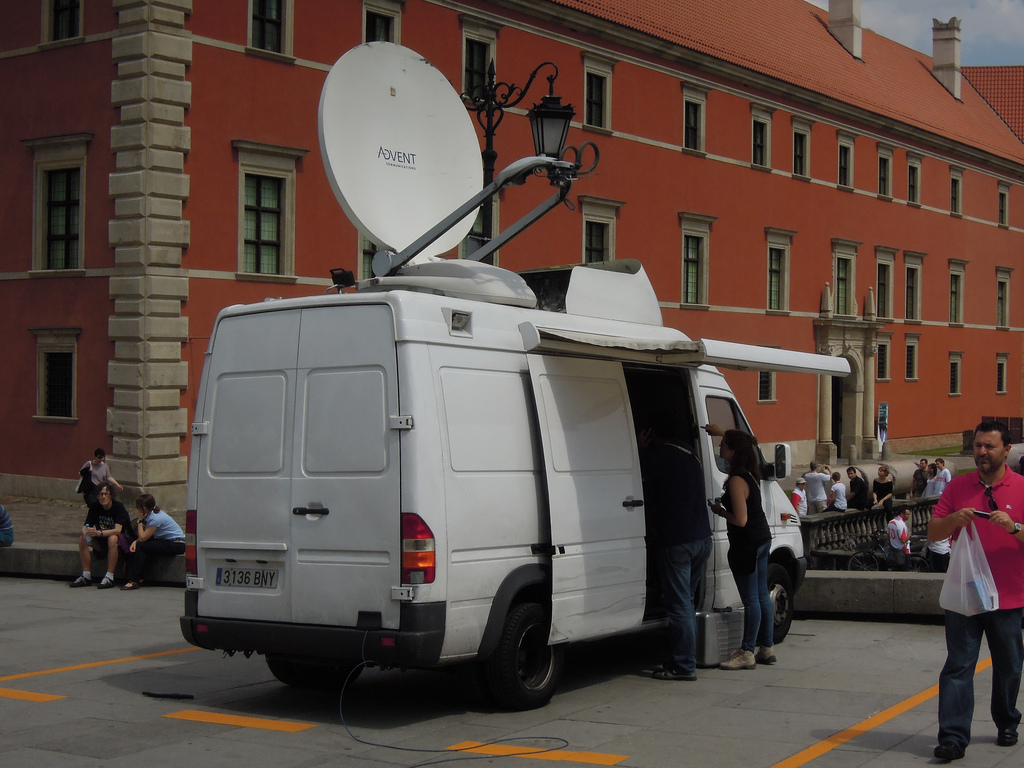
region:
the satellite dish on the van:
[296, 29, 600, 296]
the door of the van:
[512, 341, 653, 659]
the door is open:
[515, 351, 665, 643]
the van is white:
[176, 279, 856, 701]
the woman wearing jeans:
[701, 420, 797, 673]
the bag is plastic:
[935, 516, 1013, 619]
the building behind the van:
[2, 7, 1021, 498]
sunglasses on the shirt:
[973, 481, 1005, 521]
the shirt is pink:
[926, 468, 1021, 609]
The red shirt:
[924, 463, 1022, 620]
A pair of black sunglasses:
[973, 482, 1009, 521]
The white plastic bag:
[935, 523, 1006, 626]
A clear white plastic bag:
[934, 521, 1005, 630]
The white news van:
[167, 263, 841, 687]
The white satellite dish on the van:
[290, 39, 509, 255]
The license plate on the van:
[192, 554, 288, 606]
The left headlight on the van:
[172, 515, 205, 574]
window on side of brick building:
[43, 352, 74, 417]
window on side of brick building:
[246, 170, 288, 273]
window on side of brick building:
[248, 0, 290, 54]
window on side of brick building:
[464, 32, 493, 97]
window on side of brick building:
[585, 217, 612, 266]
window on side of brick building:
[680, 228, 707, 304]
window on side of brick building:
[754, 116, 769, 167]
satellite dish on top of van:
[301, 36, 489, 255]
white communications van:
[239, 274, 736, 686]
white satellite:
[327, 56, 511, 253]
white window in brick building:
[567, 65, 625, 142]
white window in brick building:
[200, 125, 305, 239]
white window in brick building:
[554, 170, 616, 251]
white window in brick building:
[662, 201, 705, 309]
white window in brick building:
[747, 227, 795, 313]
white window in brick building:
[715, 65, 776, 192]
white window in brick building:
[817, 236, 868, 328]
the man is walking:
[928, 417, 1021, 757]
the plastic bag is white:
[936, 516, 1000, 615]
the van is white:
[178, 41, 850, 699]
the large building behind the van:
[0, 0, 1022, 709]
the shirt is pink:
[930, 462, 1022, 609]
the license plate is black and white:
[213, 566, 281, 590]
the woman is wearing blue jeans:
[697, 420, 777, 670]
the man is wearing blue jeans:
[920, 421, 1022, 763]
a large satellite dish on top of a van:
[310, 23, 510, 279]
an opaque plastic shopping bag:
[923, 527, 1006, 622]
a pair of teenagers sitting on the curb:
[63, 476, 197, 598]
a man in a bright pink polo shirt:
[917, 411, 1022, 766]